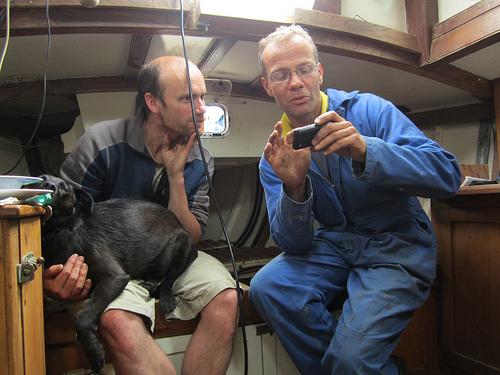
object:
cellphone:
[291, 124, 324, 150]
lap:
[210, 286, 239, 315]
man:
[44, 56, 239, 374]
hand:
[42, 252, 91, 302]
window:
[199, 104, 228, 133]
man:
[249, 25, 464, 375]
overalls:
[247, 89, 462, 374]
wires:
[0, 0, 52, 176]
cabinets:
[104, 319, 304, 375]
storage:
[0, 0, 500, 375]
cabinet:
[0, 200, 52, 375]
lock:
[16, 251, 47, 283]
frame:
[3, 0, 493, 138]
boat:
[1, 0, 498, 375]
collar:
[280, 90, 328, 148]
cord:
[1, 1, 12, 71]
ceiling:
[3, 6, 500, 131]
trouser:
[249, 213, 437, 374]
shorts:
[98, 249, 242, 335]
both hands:
[263, 110, 366, 186]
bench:
[42, 279, 256, 345]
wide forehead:
[261, 35, 313, 66]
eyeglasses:
[264, 60, 319, 83]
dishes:
[0, 188, 53, 200]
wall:
[46, 89, 283, 159]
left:
[57, 0, 232, 375]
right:
[240, 12, 468, 375]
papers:
[460, 175, 495, 186]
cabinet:
[423, 183, 499, 374]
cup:
[0, 175, 43, 189]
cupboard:
[1, 204, 45, 375]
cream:
[187, 271, 210, 286]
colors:
[0, 191, 52, 292]